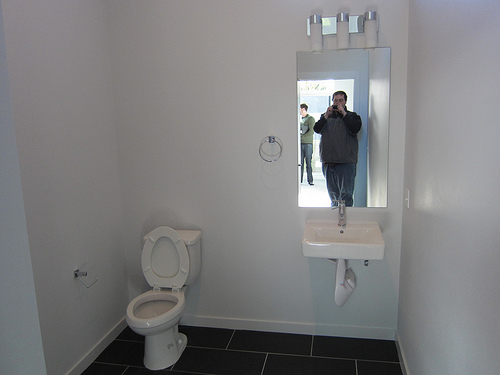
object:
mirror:
[290, 43, 393, 210]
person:
[313, 89, 365, 209]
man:
[315, 89, 356, 207]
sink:
[302, 220, 387, 273]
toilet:
[125, 224, 205, 374]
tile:
[66, 315, 409, 373]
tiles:
[58, 317, 402, 374]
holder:
[354, 260, 377, 269]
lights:
[295, 9, 390, 47]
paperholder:
[74, 269, 95, 289]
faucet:
[338, 200, 347, 225]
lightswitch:
[402, 188, 413, 211]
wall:
[396, 1, 499, 374]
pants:
[322, 162, 355, 207]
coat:
[317, 107, 360, 167]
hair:
[333, 88, 349, 104]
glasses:
[334, 97, 343, 102]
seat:
[139, 227, 192, 292]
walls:
[1, 2, 497, 342]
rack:
[256, 137, 282, 163]